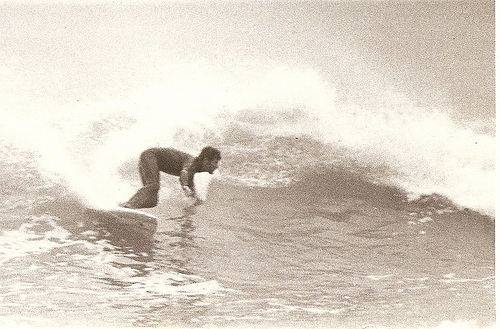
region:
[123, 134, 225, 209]
man surfing a wave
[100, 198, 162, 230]
surfboard man is on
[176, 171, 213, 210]
man's arm in the water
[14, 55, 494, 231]
wave surfer is riding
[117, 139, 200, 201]
dark colored wetsuit of surfer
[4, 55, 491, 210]
white foam of the wave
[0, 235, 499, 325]
calm area in front of wave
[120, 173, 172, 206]
legs of surfer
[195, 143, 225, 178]
face of surfer looking away from camera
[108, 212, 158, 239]
bottom of surfboard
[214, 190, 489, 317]
The water is brown.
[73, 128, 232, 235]
He is surfing.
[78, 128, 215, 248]
He is on a surf board.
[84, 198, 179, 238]
The surf board is white.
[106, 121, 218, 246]
He is leaning in.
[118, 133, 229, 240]
He is in the water.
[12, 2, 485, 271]
The wave is large.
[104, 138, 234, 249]
He is wearing a wet suit.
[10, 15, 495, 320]
He is in the ocean.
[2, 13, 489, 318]
He is surfing alone.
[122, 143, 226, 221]
a man on a surfboard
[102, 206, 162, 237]
the nose of a surfboard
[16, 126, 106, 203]
a surfboard shooting water off of it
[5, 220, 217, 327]
white foam on calm water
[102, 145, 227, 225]
a man surfing a wave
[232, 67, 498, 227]
a white crashing wave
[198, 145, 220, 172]
the head of a man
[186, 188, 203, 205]
a man's hand in water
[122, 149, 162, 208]
legs of a surfer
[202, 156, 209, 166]
the ear of a man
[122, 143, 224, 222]
a man leaning on a surfboard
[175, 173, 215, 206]
a man's hand in water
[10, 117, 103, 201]
water shot off of a surfboard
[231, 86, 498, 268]
white waves crashing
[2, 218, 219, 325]
foam on calm water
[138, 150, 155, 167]
a man's butt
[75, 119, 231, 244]
man of surf board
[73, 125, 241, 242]
man surfing the waves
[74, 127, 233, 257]
man on white surfboard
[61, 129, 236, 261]
surfer dragging hand in water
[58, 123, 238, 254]
surfer with dark hair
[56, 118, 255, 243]
surfer with long pants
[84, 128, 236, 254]
surfer with long sleeved shirt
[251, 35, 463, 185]
ocean spray from waves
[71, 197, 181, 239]
light colored surf board in water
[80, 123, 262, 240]
dark haired man in ocean on surfboard